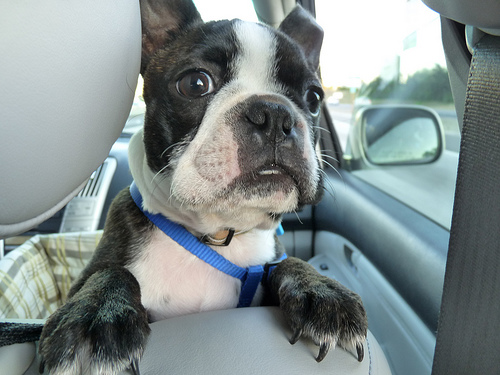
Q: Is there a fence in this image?
A: No, there are no fences.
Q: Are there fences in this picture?
A: No, there are no fences.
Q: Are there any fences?
A: No, there are no fences.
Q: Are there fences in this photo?
A: No, there are no fences.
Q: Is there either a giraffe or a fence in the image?
A: No, there are no fences or giraffes.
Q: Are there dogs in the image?
A: Yes, there is a dog.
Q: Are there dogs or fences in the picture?
A: Yes, there is a dog.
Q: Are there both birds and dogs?
A: No, there is a dog but no birds.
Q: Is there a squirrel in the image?
A: No, there are no squirrels.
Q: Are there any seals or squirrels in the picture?
A: No, there are no squirrels or seals.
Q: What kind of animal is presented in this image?
A: The animal is a dog.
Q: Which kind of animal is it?
A: The animal is a dog.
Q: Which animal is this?
A: This is a dog.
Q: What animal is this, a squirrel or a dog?
A: This is a dog.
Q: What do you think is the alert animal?
A: The animal is a dog.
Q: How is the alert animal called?
A: The animal is a dog.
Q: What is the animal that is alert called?
A: The animal is a dog.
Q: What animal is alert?
A: The animal is a dog.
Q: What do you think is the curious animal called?
A: The animal is a dog.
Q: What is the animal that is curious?
A: The animal is a dog.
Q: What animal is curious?
A: The animal is a dog.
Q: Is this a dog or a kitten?
A: This is a dog.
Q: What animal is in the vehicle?
A: The animal is a dog.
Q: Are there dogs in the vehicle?
A: Yes, there is a dog in the vehicle.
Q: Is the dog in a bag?
A: No, the dog is in the vehicle.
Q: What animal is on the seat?
A: The dog is on the seat.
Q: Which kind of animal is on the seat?
A: The animal is a dog.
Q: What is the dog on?
A: The dog is on the seat.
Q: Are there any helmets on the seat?
A: No, there is a dog on the seat.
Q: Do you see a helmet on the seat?
A: No, there is a dog on the seat.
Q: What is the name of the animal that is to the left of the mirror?
A: The animal is a dog.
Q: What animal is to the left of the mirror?
A: The animal is a dog.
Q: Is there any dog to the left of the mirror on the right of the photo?
A: Yes, there is a dog to the left of the mirror.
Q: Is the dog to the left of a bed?
A: No, the dog is to the left of the mirror.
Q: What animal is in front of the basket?
A: The dog is in front of the basket.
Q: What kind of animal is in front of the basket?
A: The animal is a dog.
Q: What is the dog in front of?
A: The dog is in front of the basket.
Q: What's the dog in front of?
A: The dog is in front of the basket.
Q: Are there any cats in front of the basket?
A: No, there is a dog in front of the basket.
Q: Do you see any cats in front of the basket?
A: No, there is a dog in front of the basket.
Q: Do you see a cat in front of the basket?
A: No, there is a dog in front of the basket.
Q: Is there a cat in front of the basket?
A: No, there is a dog in front of the basket.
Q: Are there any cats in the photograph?
A: No, there are no cats.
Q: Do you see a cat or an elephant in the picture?
A: No, there are no cats or elephants.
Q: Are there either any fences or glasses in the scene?
A: No, there are no fences or glasses.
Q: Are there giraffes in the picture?
A: No, there are no giraffes.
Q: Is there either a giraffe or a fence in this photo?
A: No, there are no giraffes or fences.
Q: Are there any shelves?
A: No, there are no shelves.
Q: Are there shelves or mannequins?
A: No, there are no shelves or mannequins.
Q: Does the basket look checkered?
A: Yes, the basket is checkered.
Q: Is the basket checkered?
A: Yes, the basket is checkered.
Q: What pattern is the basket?
A: The basket is checkered.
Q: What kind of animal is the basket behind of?
A: The basket is behind the dog.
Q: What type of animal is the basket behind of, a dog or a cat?
A: The basket is behind a dog.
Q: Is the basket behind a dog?
A: Yes, the basket is behind a dog.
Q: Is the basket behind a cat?
A: No, the basket is behind a dog.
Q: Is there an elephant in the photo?
A: No, there are no elephants.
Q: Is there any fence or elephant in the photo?
A: No, there are no elephants or fences.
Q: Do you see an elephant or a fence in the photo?
A: No, there are no elephants or fences.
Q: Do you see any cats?
A: No, there are no cats.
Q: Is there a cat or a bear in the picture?
A: No, there are no cats or bears.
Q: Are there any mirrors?
A: Yes, there is a mirror.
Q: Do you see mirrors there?
A: Yes, there is a mirror.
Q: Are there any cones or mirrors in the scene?
A: Yes, there is a mirror.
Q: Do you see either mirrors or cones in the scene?
A: Yes, there is a mirror.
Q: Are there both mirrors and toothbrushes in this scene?
A: No, there is a mirror but no toothbrushes.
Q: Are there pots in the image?
A: No, there are no pots.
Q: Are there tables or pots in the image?
A: No, there are no pots or tables.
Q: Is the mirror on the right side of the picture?
A: Yes, the mirror is on the right of the image.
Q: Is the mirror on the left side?
A: No, the mirror is on the right of the image.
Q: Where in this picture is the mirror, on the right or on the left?
A: The mirror is on the right of the image.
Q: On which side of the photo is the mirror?
A: The mirror is on the right of the image.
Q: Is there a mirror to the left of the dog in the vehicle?
A: No, the mirror is to the right of the dog.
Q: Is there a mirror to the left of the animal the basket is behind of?
A: No, the mirror is to the right of the dog.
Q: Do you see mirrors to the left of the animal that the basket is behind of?
A: No, the mirror is to the right of the dog.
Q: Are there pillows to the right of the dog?
A: No, there is a mirror to the right of the dog.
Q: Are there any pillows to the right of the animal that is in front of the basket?
A: No, there is a mirror to the right of the dog.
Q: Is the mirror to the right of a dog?
A: Yes, the mirror is to the right of a dog.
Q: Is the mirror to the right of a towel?
A: No, the mirror is to the right of a dog.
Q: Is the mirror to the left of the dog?
A: No, the mirror is to the right of the dog.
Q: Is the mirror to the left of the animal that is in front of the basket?
A: No, the mirror is to the right of the dog.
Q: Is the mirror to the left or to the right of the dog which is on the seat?
A: The mirror is to the right of the dog.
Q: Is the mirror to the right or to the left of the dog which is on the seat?
A: The mirror is to the right of the dog.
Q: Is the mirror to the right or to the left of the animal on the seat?
A: The mirror is to the right of the dog.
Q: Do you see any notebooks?
A: No, there are no notebooks.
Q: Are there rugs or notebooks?
A: No, there are no notebooks or rugs.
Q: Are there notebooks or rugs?
A: No, there are no notebooks or rugs.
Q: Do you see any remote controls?
A: Yes, there is a remote control.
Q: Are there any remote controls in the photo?
A: Yes, there is a remote control.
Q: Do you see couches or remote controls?
A: Yes, there is a remote control.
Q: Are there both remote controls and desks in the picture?
A: No, there is a remote control but no desks.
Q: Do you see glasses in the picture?
A: No, there are no glasses.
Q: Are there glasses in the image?
A: No, there are no glasses.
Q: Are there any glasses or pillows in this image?
A: No, there are no glasses or pillows.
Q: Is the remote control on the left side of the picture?
A: Yes, the remote control is on the left of the image.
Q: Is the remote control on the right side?
A: No, the remote control is on the left of the image.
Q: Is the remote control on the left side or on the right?
A: The remote control is on the left of the image.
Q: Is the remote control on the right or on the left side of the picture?
A: The remote control is on the left of the image.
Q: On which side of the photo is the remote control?
A: The remote control is on the left of the image.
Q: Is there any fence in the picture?
A: No, there are no fences.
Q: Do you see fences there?
A: No, there are no fences.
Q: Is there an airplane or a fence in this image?
A: No, there are no fences or airplanes.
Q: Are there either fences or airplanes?
A: No, there are no fences or airplanes.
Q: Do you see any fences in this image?
A: No, there are no fences.